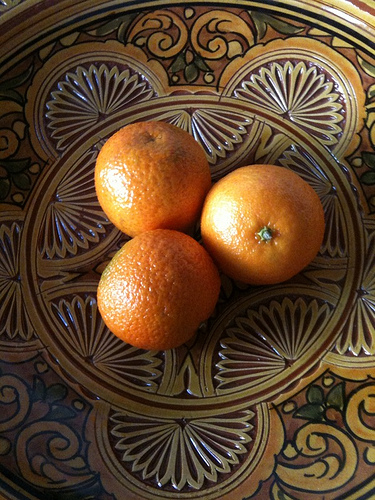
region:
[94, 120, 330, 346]
Group of oranges on tile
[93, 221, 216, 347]
Small orange with bumpy skin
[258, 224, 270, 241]
Green hard stem on orange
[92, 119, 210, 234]
Orange with brown spot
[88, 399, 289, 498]
Shiny half moon shape tile design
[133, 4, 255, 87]
Curved designs on tile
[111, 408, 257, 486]
Peacock feather shaped design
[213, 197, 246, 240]
Light reflection on orange skin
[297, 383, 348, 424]
Painted green leaf design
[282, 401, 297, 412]
Black outlined circle design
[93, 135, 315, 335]
three small oranges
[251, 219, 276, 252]
green stem of an orange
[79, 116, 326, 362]
oranges on a plate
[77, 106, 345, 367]
oranges on a brown decorative plate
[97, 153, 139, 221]
reflection of light on an orange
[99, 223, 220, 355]
orange with speckled rind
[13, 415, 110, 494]
decorative pattern on a plate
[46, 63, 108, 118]
shiny ceramic plate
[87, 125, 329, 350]
oranges on a ceramic plate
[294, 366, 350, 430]
leaf pattern on a plate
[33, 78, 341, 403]
three oranges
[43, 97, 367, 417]
three oranges that are together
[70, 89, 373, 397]
three fresh oranges together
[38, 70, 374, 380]
three oranges next to each other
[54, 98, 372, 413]
oranges on a table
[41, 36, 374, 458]
three oranges on a table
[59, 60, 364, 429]
fresh oranges next to each other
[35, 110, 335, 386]
three fresh oranges on a table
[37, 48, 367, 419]
a table with oranges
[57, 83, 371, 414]
a table with three oranges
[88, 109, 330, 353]
Three oranges touching each other.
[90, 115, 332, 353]
Three pieces of fruit on a decorative background.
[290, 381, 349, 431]
A green object that looks like a leaf.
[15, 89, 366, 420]
A big decorative circle.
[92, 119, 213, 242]
A bruised piece of fruit.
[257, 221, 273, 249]
A stem on the top of an orange.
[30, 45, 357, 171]
Two shapes that look like ears.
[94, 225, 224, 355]
An orange turned sideways.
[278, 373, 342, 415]
Two small objects that look like ovals.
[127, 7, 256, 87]
Tan and green paint.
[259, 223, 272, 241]
Hard green stem on orange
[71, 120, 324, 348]
Group of oranges on tile plate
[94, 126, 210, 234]
Orange with light brown on skin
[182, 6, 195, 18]
Black outlined teardrop design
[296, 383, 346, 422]
Green leaf design on plate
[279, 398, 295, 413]
Small circle design with black outline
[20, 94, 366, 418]
Large brown circle design under oranges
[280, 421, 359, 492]
Spiral curve design on plate